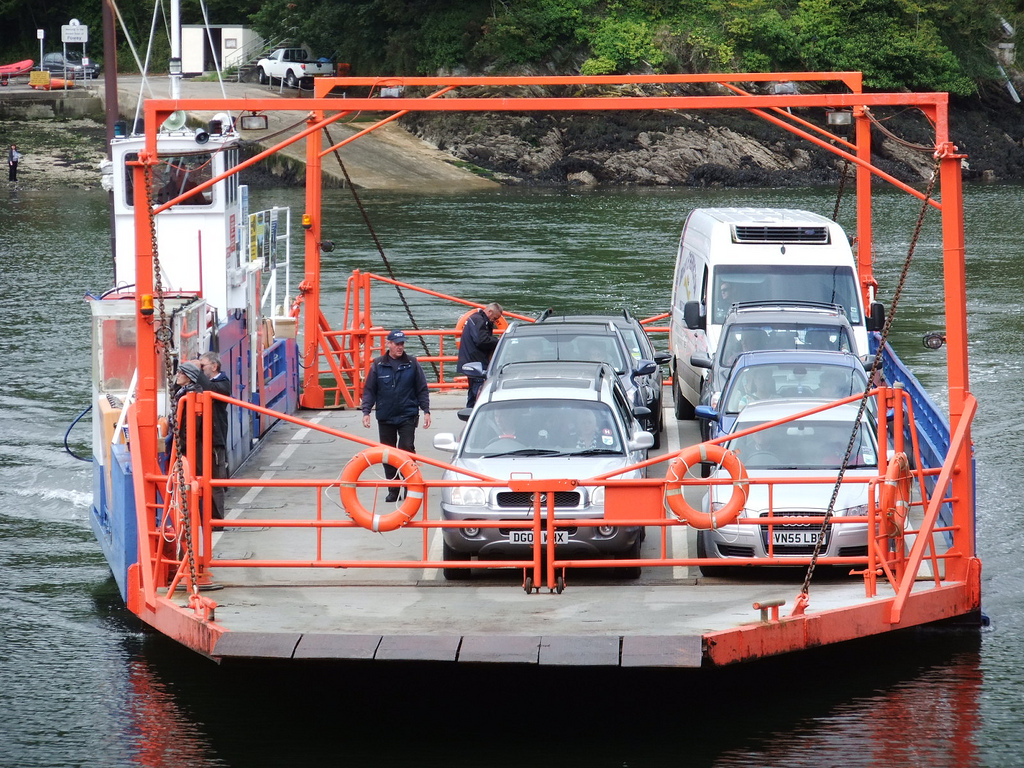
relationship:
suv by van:
[706, 286, 862, 380] [637, 173, 890, 398]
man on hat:
[351, 315, 436, 493] [382, 326, 411, 348]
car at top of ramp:
[40, 45, 99, 78] [5, 67, 498, 186]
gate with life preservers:
[198, 392, 911, 652] [324, 448, 485, 557]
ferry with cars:
[87, 69, 984, 678] [397, 229, 966, 660]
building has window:
[80, 125, 307, 609] [147, 173, 214, 206]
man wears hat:
[351, 315, 436, 493] [378, 319, 407, 345]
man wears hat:
[352, 315, 437, 493] [374, 319, 414, 348]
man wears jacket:
[351, 315, 436, 493] [348, 356, 437, 426]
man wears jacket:
[352, 315, 437, 493] [356, 360, 437, 427]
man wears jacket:
[351, 315, 436, 493] [359, 360, 437, 434]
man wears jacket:
[351, 315, 436, 493] [359, 356, 433, 423]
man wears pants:
[351, 315, 436, 493] [367, 416, 430, 490]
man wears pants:
[351, 315, 436, 493] [374, 423, 429, 497]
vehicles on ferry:
[419, 188, 921, 593] [69, 39, 1003, 765]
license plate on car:
[758, 509, 832, 546] [687, 389, 914, 578]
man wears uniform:
[351, 315, 436, 493] [363, 360, 430, 471]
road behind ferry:
[270, 118, 474, 188] [69, 39, 1003, 765]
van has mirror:
[650, 193, 886, 427] [672, 289, 712, 337]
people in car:
[478, 408, 619, 452] [430, 378, 660, 590]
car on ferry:
[430, 378, 660, 590] [69, 39, 1003, 765]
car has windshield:
[702, 335, 884, 431] [720, 362, 868, 399]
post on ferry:
[841, 68, 880, 328] [87, 68, 980, 671]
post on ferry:
[930, 87, 978, 582] [87, 68, 980, 671]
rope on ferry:
[860, 102, 947, 154] [87, 68, 980, 671]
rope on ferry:
[802, 152, 945, 595] [87, 68, 980, 671]